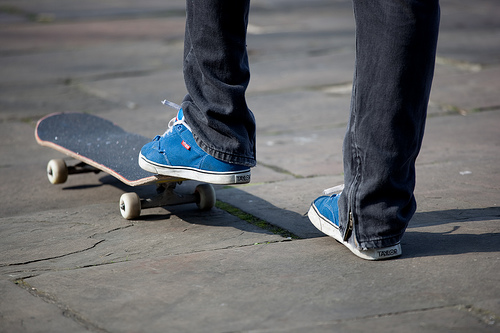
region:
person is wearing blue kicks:
[139, 105, 406, 262]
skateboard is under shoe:
[36, 111, 216, 218]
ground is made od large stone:
[0, 1, 499, 330]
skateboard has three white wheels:
[44, 153, 216, 220]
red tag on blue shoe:
[178, 140, 193, 151]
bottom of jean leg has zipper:
[338, 148, 363, 254]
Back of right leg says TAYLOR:
[374, 244, 404, 261]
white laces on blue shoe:
[154, 94, 191, 138]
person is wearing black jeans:
[181, 2, 440, 253]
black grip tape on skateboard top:
[38, 115, 197, 183]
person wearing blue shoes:
[123, 108, 245, 198]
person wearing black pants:
[363, 3, 449, 255]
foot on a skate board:
[135, 137, 242, 203]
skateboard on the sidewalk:
[26, 94, 211, 220]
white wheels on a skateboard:
[110, 192, 147, 221]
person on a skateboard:
[38, 70, 273, 218]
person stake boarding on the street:
[34, 89, 229, 244]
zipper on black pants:
[345, 150, 374, 254]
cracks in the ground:
[232, 208, 304, 263]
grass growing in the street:
[224, 200, 286, 241]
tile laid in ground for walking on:
[23, 261, 394, 328]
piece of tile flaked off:
[11, 246, 89, 262]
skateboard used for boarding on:
[38, 108, 135, 195]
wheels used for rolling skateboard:
[42, 160, 70, 182]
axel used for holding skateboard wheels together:
[68, 163, 85, 173]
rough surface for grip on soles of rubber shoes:
[54, 115, 108, 146]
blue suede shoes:
[156, 134, 198, 159]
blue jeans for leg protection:
[358, 50, 404, 233]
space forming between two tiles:
[221, 203, 278, 239]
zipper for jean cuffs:
[347, 155, 362, 239]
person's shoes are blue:
[127, 96, 410, 265]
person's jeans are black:
[168, 4, 458, 253]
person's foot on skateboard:
[120, 83, 260, 199]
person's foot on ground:
[298, 183, 411, 273]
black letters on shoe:
[368, 237, 402, 268]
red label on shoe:
[173, 130, 200, 160]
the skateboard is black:
[21, 98, 206, 220]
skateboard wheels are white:
[26, 143, 244, 236]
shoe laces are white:
[152, 96, 202, 141]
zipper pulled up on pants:
[339, 201, 369, 251]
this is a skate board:
[26, 95, 233, 255]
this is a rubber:
[122, 94, 247, 208]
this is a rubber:
[294, 133, 401, 285]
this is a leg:
[159, 3, 277, 167]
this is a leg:
[319, 18, 448, 270]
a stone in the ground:
[196, 225, 318, 307]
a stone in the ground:
[258, 38, 325, 139]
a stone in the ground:
[463, 124, 498, 206]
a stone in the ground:
[193, 286, 270, 329]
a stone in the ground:
[82, 245, 164, 315]